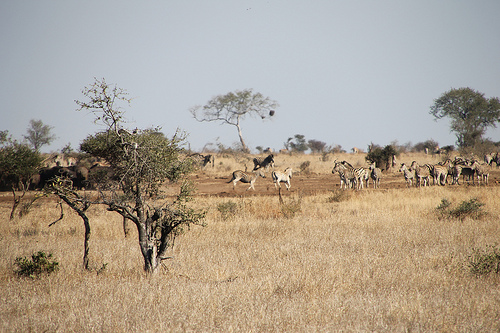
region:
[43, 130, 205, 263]
Green and brown bushes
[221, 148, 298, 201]
Animals running in brush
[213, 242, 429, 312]
Tall brown brush on ground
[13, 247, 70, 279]
Small green bush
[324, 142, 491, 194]
Large herd of animals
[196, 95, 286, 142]
Tall tree in the background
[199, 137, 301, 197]
A few animals running quickly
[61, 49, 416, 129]
Large grey clear sky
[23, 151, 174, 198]
Large safari animals hidden from view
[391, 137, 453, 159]
Animals in the far background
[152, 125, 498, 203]
animals in the plains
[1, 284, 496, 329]
brown grasses in the plains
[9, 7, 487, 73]
greyish blue sky in the distance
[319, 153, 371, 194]
zebras in the plains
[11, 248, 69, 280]
bush with green leaves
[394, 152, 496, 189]
cluster of zebras in the plains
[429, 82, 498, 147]
tree at the edge of plain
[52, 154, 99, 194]
animals behind the trees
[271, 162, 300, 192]
zebra running in the plains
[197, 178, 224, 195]
dirt ground where animals are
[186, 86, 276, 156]
A tree on the picture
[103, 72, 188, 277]
A tree on the picture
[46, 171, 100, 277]
A tree on the picture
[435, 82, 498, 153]
A tree on the picture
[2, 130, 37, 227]
A tree on the picture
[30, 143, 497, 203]
Animals on the picture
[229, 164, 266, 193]
Zebra in the picture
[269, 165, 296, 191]
Zebra in the picture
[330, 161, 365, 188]
Zebra in the picture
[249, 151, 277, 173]
Zebra in the picture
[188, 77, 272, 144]
an african tree with no leaves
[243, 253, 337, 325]
dead brown grass in africa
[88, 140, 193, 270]
a dry dead brown tree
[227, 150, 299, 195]
two zebras running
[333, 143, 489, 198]
a large group of standing zebra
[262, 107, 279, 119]
a brown nest in a barren tree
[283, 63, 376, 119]
hazy bluish sky over the plains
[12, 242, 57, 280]
a small green bush in dead grass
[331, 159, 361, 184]
a giraffe looking to the left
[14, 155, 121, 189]
a dark brown rock formation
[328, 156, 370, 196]
a zebra on the grass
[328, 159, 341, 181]
the head of a zebra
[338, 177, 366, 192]
the legs of a zebra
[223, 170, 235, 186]
the tail of a zebra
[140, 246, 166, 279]
the trunk of a tree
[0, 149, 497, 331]
a yellow grassy field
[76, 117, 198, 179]
a green tree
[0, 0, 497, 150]
a gray sky overhead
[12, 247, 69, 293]
a small green shrub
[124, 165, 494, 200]
a patch of dirt